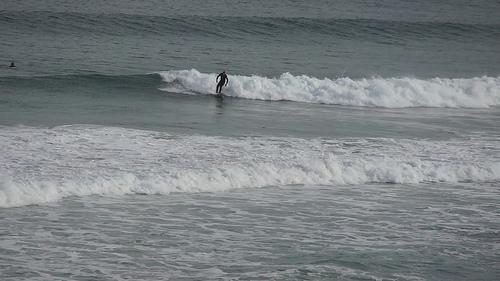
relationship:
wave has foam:
[34, 69, 490, 123] [168, 68, 498, 111]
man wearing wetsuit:
[212, 66, 233, 93] [215, 74, 230, 92]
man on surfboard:
[212, 66, 233, 93] [212, 87, 228, 98]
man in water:
[7, 60, 20, 75] [2, 3, 499, 280]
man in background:
[7, 60, 20, 75] [2, 3, 466, 112]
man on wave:
[212, 66, 233, 93] [34, 69, 490, 123]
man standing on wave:
[212, 66, 233, 93] [34, 69, 490, 123]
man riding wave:
[212, 66, 233, 93] [34, 69, 490, 123]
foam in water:
[168, 68, 498, 111] [2, 3, 499, 280]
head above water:
[8, 60, 16, 65] [2, 3, 499, 280]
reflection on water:
[4, 10, 499, 58] [2, 3, 499, 280]